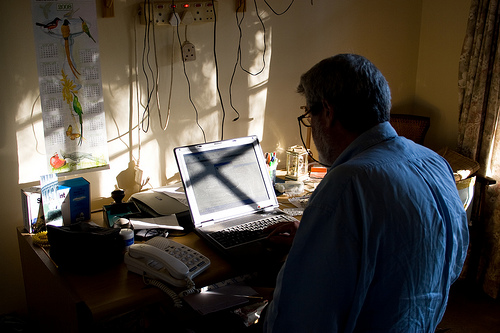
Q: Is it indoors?
A: Yes, it is indoors.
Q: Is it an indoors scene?
A: Yes, it is indoors.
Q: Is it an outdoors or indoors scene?
A: It is indoors.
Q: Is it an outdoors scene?
A: No, it is indoors.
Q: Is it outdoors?
A: No, it is indoors.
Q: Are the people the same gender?
A: No, they are both male and female.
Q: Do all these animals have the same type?
A: No, there are both birds and bugs.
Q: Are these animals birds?
A: No, there are both birds and bugs.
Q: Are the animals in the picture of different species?
A: Yes, they are birds and bugs.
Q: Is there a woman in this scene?
A: Yes, there is a woman.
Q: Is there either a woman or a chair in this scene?
A: Yes, there is a woman.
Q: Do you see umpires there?
A: No, there are no umpires.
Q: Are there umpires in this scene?
A: No, there are no umpires.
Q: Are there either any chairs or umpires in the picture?
A: No, there are no umpires or chairs.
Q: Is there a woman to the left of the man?
A: Yes, there is a woman to the left of the man.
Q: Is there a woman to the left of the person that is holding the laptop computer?
A: Yes, there is a woman to the left of the man.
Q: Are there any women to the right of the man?
A: No, the woman is to the left of the man.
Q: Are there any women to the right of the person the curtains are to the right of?
A: No, the woman is to the left of the man.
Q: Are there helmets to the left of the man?
A: No, there is a woman to the left of the man.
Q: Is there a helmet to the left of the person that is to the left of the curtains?
A: No, there is a woman to the left of the man.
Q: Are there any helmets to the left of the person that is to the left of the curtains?
A: No, there is a woman to the left of the man.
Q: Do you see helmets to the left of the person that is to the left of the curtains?
A: No, there is a woman to the left of the man.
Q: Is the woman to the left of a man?
A: Yes, the woman is to the left of a man.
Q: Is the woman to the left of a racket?
A: No, the woman is to the left of a man.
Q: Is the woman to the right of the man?
A: No, the woman is to the left of the man.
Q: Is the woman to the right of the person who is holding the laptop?
A: No, the woman is to the left of the man.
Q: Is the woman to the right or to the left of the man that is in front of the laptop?
A: The woman is to the left of the man.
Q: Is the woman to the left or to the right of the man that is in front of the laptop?
A: The woman is to the left of the man.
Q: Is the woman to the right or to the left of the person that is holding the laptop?
A: The woman is to the left of the man.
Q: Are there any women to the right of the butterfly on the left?
A: Yes, there is a woman to the right of the butterfly.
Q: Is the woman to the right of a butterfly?
A: Yes, the woman is to the right of a butterfly.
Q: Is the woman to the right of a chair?
A: No, the woman is to the right of a butterfly.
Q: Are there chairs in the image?
A: No, there are no chairs.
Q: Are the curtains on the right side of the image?
A: Yes, the curtains are on the right of the image.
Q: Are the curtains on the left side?
A: No, the curtains are on the right of the image.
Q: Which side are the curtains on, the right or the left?
A: The curtains are on the right of the image.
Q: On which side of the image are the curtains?
A: The curtains are on the right of the image.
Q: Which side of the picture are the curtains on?
A: The curtains are on the right of the image.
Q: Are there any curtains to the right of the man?
A: Yes, there are curtains to the right of the man.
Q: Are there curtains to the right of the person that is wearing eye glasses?
A: Yes, there are curtains to the right of the man.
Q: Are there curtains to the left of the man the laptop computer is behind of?
A: No, the curtains are to the right of the man.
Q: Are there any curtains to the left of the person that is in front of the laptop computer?
A: No, the curtains are to the right of the man.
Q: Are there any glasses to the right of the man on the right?
A: No, there are curtains to the right of the man.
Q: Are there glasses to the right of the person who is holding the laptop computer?
A: No, there are curtains to the right of the man.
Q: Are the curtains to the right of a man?
A: Yes, the curtains are to the right of a man.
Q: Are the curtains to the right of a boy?
A: No, the curtains are to the right of a man.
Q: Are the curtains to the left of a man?
A: No, the curtains are to the right of a man.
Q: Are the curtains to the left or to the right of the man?
A: The curtains are to the right of the man.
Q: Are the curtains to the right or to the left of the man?
A: The curtains are to the right of the man.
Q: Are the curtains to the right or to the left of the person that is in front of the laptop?
A: The curtains are to the right of the man.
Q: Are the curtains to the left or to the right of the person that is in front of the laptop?
A: The curtains are to the right of the man.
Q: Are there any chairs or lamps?
A: No, there are no chairs or lamps.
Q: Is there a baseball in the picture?
A: No, there are no baseballs.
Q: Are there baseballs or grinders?
A: No, there are no baseballs or grinders.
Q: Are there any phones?
A: Yes, there is a phone.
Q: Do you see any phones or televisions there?
A: Yes, there is a phone.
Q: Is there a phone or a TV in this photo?
A: Yes, there is a phone.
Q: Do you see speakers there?
A: No, there are no speakers.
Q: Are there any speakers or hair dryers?
A: No, there are no speakers or hair dryers.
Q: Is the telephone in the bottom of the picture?
A: Yes, the telephone is in the bottom of the image.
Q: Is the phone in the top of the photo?
A: No, the phone is in the bottom of the image.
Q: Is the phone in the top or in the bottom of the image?
A: The phone is in the bottom of the image.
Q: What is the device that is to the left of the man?
A: The device is a phone.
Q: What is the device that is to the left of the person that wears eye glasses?
A: The device is a phone.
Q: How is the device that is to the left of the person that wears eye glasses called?
A: The device is a phone.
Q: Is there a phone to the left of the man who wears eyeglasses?
A: Yes, there is a phone to the left of the man.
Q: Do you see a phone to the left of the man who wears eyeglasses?
A: Yes, there is a phone to the left of the man.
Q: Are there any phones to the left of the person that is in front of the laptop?
A: Yes, there is a phone to the left of the man.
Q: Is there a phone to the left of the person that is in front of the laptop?
A: Yes, there is a phone to the left of the man.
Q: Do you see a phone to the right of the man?
A: No, the phone is to the left of the man.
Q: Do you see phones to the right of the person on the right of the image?
A: No, the phone is to the left of the man.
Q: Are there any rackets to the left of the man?
A: No, there is a phone to the left of the man.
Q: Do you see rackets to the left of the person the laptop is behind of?
A: No, there is a phone to the left of the man.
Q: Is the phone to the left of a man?
A: Yes, the phone is to the left of a man.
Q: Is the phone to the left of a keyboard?
A: No, the phone is to the left of a man.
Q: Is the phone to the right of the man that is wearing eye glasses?
A: No, the phone is to the left of the man.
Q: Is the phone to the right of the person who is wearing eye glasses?
A: No, the phone is to the left of the man.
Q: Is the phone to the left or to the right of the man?
A: The phone is to the left of the man.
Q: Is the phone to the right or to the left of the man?
A: The phone is to the left of the man.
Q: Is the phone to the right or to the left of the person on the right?
A: The phone is to the left of the man.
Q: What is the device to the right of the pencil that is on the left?
A: The device is a phone.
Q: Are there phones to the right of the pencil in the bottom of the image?
A: Yes, there is a phone to the right of the pencil.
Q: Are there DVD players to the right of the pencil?
A: No, there is a phone to the right of the pencil.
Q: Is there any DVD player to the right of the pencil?
A: No, there is a phone to the right of the pencil.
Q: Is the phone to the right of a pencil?
A: Yes, the phone is to the right of a pencil.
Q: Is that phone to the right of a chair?
A: No, the phone is to the right of a pencil.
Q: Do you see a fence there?
A: No, there are no fences.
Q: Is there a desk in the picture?
A: Yes, there is a desk.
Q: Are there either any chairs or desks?
A: Yes, there is a desk.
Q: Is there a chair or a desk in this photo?
A: Yes, there is a desk.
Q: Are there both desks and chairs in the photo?
A: No, there is a desk but no chairs.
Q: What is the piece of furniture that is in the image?
A: The piece of furniture is a desk.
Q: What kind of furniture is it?
A: The piece of furniture is a desk.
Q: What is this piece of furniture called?
A: This is a desk.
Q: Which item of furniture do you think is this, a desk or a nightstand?
A: This is a desk.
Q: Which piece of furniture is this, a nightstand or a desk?
A: This is a desk.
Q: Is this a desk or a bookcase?
A: This is a desk.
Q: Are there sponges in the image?
A: No, there are no sponges.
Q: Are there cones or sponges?
A: No, there are no sponges or cones.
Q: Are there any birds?
A: Yes, there are birds.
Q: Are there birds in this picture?
A: Yes, there are birds.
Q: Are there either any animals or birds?
A: Yes, there are birds.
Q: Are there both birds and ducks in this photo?
A: No, there are birds but no ducks.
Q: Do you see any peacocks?
A: No, there are no peacocks.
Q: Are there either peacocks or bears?
A: No, there are no peacocks or bears.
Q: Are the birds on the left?
A: Yes, the birds are on the left of the image.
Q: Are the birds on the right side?
A: No, the birds are on the left of the image.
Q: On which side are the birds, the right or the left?
A: The birds are on the left of the image.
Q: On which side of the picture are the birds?
A: The birds are on the left of the image.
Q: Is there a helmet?
A: No, there are no helmets.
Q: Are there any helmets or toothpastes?
A: No, there are no helmets or toothpastes.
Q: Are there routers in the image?
A: No, there are no routers.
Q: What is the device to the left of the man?
A: The device is a screen.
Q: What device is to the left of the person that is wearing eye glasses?
A: The device is a screen.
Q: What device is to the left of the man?
A: The device is a screen.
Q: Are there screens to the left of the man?
A: Yes, there is a screen to the left of the man.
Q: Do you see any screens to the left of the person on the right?
A: Yes, there is a screen to the left of the man.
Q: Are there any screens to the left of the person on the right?
A: Yes, there is a screen to the left of the man.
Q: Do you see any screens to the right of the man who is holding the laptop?
A: No, the screen is to the left of the man.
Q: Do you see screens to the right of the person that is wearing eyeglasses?
A: No, the screen is to the left of the man.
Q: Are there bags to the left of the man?
A: No, there is a screen to the left of the man.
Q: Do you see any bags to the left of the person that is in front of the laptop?
A: No, there is a screen to the left of the man.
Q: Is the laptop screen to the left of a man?
A: Yes, the screen is to the left of a man.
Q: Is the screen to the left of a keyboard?
A: No, the screen is to the left of a man.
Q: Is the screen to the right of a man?
A: No, the screen is to the left of a man.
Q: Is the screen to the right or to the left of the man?
A: The screen is to the left of the man.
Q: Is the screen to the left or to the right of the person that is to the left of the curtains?
A: The screen is to the left of the man.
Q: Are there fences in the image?
A: No, there are no fences.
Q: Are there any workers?
A: No, there are no workers.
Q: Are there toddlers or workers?
A: No, there are no workers or toddlers.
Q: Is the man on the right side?
A: Yes, the man is on the right of the image.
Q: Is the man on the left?
A: No, the man is on the right of the image.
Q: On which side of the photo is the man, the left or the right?
A: The man is on the right of the image.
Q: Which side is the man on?
A: The man is on the right of the image.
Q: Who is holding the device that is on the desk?
A: The man is holding the laptop.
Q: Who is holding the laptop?
A: The man is holding the laptop.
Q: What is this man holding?
A: The man is holding the laptop.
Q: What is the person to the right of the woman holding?
A: The man is holding the laptop.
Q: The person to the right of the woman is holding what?
A: The man is holding the laptop.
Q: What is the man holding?
A: The man is holding the laptop.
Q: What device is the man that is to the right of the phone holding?
A: The man is holding the laptop.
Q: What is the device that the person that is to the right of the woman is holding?
A: The device is a laptop.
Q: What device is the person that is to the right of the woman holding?
A: The man is holding the laptop.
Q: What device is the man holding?
A: The man is holding the laptop.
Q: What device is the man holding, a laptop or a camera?
A: The man is holding a laptop.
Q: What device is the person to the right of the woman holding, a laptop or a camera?
A: The man is holding a laptop.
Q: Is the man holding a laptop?
A: Yes, the man is holding a laptop.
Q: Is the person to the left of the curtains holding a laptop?
A: Yes, the man is holding a laptop.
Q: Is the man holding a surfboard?
A: No, the man is holding a laptop.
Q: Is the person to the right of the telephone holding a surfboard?
A: No, the man is holding a laptop.